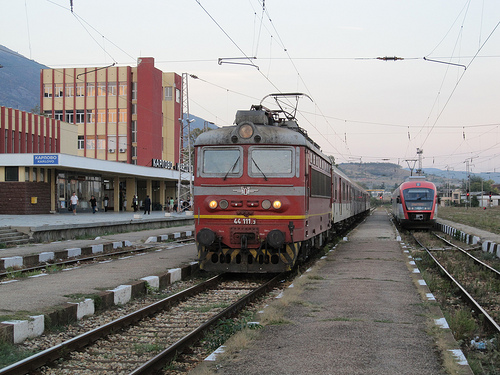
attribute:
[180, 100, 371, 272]
train — old, red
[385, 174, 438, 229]
train — newer, red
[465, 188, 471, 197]
lights — red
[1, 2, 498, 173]
sky — blue